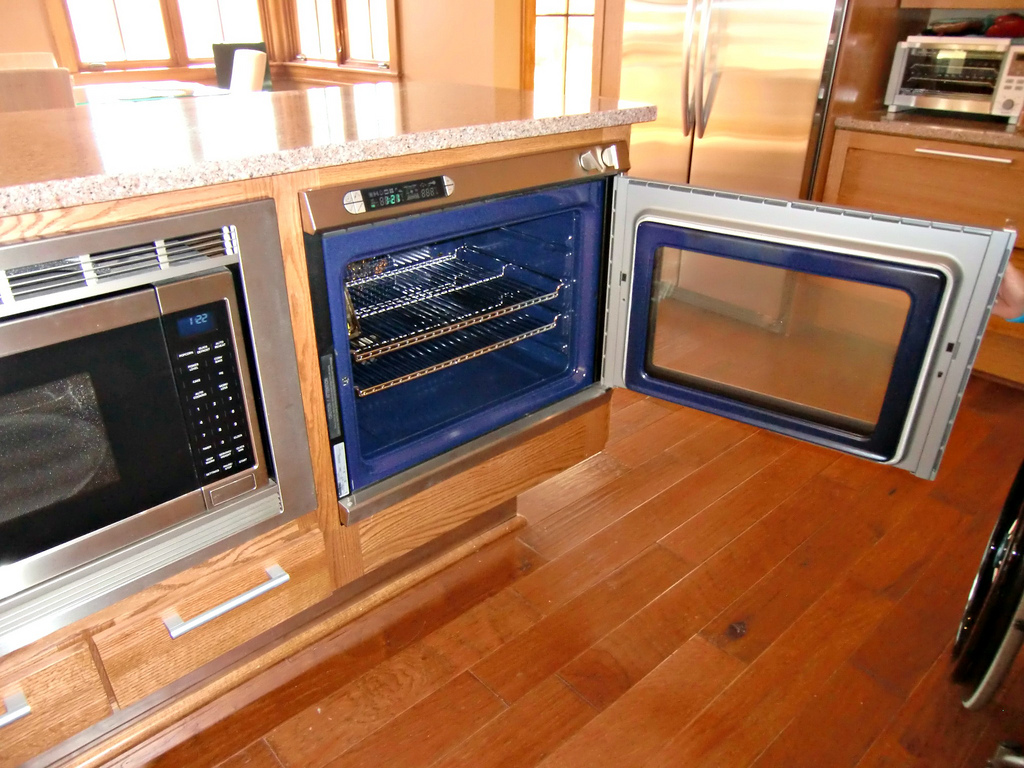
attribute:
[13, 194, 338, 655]
microwave — stainless steel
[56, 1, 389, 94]
windows — pair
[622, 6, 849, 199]
refrigerator — stainless steel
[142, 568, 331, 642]
handle — silver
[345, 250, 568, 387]
racks — metal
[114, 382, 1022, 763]
panels — hard wood, floor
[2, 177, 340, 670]
oven — silver, microwave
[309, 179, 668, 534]
blue — inside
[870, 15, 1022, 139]
oven — white, toaster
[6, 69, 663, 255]
top — stone, marble, counter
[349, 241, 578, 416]
racks — shelf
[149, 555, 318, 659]
handle — white, drawer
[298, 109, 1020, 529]
oven — convection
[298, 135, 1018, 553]
oven — convection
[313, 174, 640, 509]
interior — blue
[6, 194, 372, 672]
oven — silver, black, microwave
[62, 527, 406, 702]
drawer — wooden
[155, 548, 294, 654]
handle — metal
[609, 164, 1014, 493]
door — open, oven, white, blue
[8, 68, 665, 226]
countertop — thick, stone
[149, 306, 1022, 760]
flooring — polished, wood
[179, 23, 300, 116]
chair — white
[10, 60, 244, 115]
table — dining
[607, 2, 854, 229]
doors — aluminum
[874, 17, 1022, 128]
oven — white, toaster